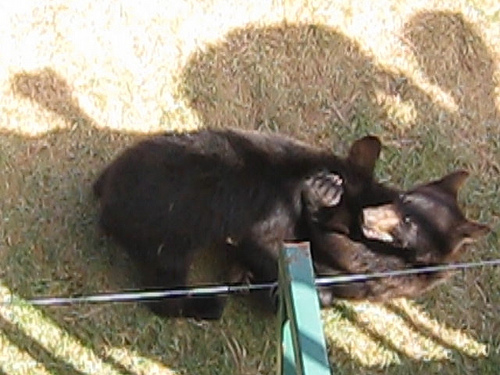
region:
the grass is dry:
[15, 136, 125, 368]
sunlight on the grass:
[42, 5, 455, 121]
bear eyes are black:
[399, 191, 426, 226]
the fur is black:
[130, 135, 393, 297]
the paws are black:
[286, 131, 383, 225]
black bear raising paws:
[81, 110, 483, 319]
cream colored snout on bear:
[353, 200, 400, 242]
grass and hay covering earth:
[0, 0, 497, 370]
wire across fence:
[5, 247, 499, 319]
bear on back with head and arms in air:
[82, 117, 495, 320]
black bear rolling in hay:
[83, 125, 476, 323]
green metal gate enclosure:
[272, 235, 351, 370]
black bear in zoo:
[81, 120, 488, 334]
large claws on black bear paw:
[305, 168, 351, 205]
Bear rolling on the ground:
[93, 127, 490, 309]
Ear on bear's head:
[445, 161, 471, 195]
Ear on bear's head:
[465, 218, 495, 243]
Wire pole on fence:
[5, 278, 293, 305]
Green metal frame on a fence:
[277, 241, 334, 372]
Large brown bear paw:
[304, 166, 344, 208]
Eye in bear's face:
[395, 211, 417, 228]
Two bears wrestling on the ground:
[94, 120, 496, 316]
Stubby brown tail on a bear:
[81, 167, 108, 205]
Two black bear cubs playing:
[90, 125, 494, 320]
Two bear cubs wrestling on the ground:
[90, 123, 493, 320]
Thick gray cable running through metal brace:
[1, 258, 499, 305]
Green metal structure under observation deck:
[272, 239, 330, 374]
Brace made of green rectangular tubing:
[272, 240, 331, 374]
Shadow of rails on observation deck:
[316, 295, 491, 368]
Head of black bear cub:
[359, 170, 494, 265]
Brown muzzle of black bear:
[361, 202, 398, 245]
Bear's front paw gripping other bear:
[303, 170, 347, 209]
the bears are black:
[80, 53, 472, 307]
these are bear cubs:
[140, 57, 470, 301]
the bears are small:
[132, 138, 461, 358]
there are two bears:
[116, 99, 487, 288]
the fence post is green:
[243, 237, 372, 349]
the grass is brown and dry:
[33, 50, 393, 121]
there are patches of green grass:
[37, 209, 174, 368]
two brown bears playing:
[115, 75, 467, 334]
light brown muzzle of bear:
[373, 173, 410, 253]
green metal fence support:
[249, 229, 356, 368]